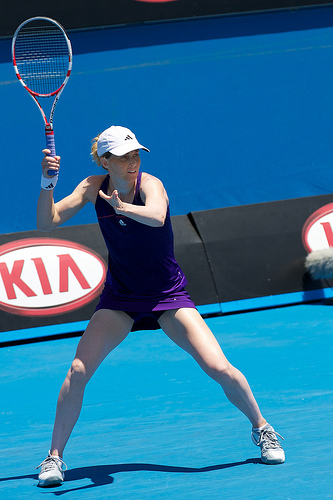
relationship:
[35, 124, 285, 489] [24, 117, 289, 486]
player has knee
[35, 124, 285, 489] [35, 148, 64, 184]
player has hand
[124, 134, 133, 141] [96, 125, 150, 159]
logo on hat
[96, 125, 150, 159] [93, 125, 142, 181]
hat on head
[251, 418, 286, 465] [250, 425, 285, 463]
shoe on foot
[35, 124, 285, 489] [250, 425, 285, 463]
player has foot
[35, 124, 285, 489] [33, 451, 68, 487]
player has foot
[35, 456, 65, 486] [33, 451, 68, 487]
shoe on foot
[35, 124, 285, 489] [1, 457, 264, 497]
player has shadow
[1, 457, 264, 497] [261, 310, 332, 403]
shadow on court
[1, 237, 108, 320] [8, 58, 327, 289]
logo on wall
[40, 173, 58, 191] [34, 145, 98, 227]
band on arm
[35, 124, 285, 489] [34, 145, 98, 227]
player has arm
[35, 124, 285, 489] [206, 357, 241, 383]
player has knee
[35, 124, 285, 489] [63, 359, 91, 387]
player has knee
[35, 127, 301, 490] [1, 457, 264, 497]
player has shadow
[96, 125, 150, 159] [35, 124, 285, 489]
hat on player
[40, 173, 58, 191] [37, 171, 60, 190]
band on wrist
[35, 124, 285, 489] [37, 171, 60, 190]
player has wrist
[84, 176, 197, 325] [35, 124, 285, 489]
suit on player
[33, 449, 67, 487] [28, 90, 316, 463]
shoe on woman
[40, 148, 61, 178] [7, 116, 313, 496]
hand on woman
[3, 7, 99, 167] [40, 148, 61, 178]
racket in hand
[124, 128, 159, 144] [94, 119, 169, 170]
logo on hat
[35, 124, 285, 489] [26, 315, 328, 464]
player on court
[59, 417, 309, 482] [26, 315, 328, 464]
shadow on court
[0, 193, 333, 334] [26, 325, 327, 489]
barrier on court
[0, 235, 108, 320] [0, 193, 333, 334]
logo on barrier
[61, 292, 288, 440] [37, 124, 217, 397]
legs on player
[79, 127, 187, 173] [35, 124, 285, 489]
hat on player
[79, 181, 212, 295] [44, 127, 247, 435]
gear on woman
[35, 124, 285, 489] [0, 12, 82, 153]
player with racket